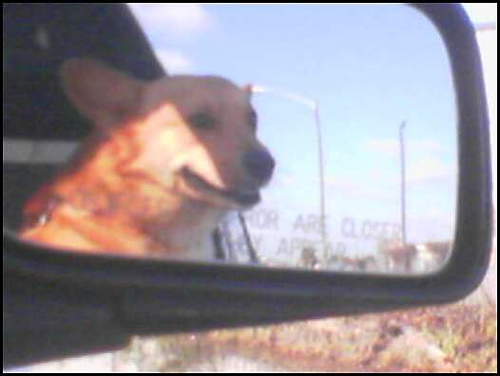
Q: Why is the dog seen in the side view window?
A: Hanging out of car window.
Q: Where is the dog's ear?
A: On head.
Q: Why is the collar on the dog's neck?
A: Find if lost.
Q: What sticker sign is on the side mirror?
A: "Closer than appear".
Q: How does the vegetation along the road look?
A: Dried out.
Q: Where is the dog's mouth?
A: Below nose.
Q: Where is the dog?
A: In a car.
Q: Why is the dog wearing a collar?
A: For identification.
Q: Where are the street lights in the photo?
A: Reflected in the mirror.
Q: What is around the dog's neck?
A: A red collar.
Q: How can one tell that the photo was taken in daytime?
A: The sky.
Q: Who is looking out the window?
A: A dog.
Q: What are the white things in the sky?
A: Clouds.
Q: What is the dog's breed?
A: Mutt.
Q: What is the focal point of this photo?
A: Rear view mirror on the drivers side of the car.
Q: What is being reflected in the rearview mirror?
A: A dog's reflection.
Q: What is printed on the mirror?
A: "Objects in mirror are closer then they appear.".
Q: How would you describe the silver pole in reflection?
A: A street light.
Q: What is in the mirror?
A: A dog.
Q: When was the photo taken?
A: Day time.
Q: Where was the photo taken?
A: A car.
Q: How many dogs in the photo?
A: One.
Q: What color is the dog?
A: Tan.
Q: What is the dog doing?
A: Smiling.